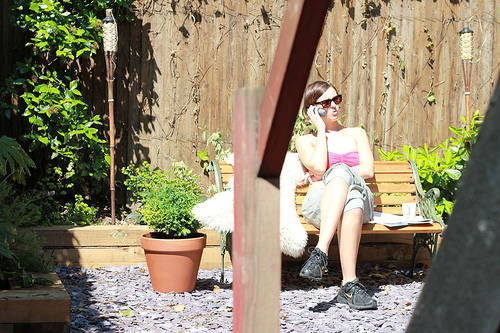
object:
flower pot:
[140, 232, 207, 293]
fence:
[76, 0, 499, 220]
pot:
[141, 232, 207, 294]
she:
[295, 81, 377, 310]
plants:
[0, 0, 113, 225]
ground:
[130, 286, 179, 331]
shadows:
[308, 294, 338, 313]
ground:
[431, 132, 454, 163]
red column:
[233, 86, 279, 333]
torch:
[101, 6, 119, 226]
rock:
[157, 321, 172, 328]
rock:
[189, 289, 203, 296]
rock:
[126, 299, 136, 304]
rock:
[221, 310, 233, 318]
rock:
[290, 319, 304, 326]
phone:
[307, 106, 326, 117]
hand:
[307, 105, 326, 129]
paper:
[370, 210, 432, 228]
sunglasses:
[309, 94, 343, 108]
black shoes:
[299, 246, 378, 310]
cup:
[402, 203, 416, 220]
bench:
[210, 158, 446, 288]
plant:
[121, 160, 208, 292]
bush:
[120, 160, 202, 235]